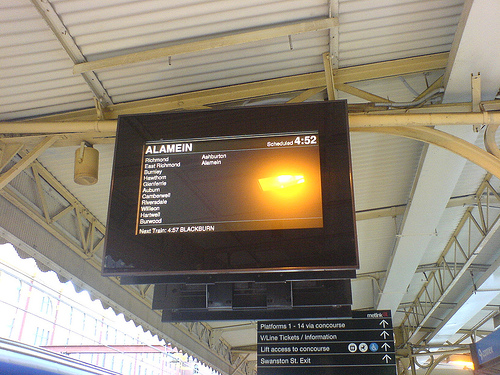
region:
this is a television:
[118, 116, 358, 273]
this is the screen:
[146, 143, 320, 218]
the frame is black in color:
[128, 108, 328, 128]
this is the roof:
[104, 21, 286, 62]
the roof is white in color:
[403, 211, 424, 245]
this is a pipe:
[382, 100, 424, 108]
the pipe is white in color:
[393, 101, 405, 107]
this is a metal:
[6, 134, 78, 225]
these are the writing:
[143, 154, 164, 224]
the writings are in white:
[148, 146, 179, 188]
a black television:
[100, 93, 364, 278]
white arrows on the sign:
[378, 313, 394, 369]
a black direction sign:
[254, 303, 399, 373]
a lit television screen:
[132, 124, 331, 246]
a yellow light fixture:
[69, 140, 102, 192]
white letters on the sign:
[258, 316, 350, 334]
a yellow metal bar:
[0, 105, 499, 140]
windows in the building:
[1, 241, 227, 373]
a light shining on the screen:
[246, 152, 322, 217]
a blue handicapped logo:
[368, 340, 380, 357]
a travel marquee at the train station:
[97, 113, 359, 276]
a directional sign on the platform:
[254, 320, 413, 374]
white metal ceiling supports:
[446, 234, 484, 269]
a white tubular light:
[74, 157, 103, 189]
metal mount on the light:
[77, 141, 83, 151]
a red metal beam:
[70, 340, 157, 356]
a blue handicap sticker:
[370, 337, 390, 357]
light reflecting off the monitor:
[243, 161, 323, 201]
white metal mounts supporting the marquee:
[321, 59, 349, 96]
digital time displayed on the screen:
[284, 129, 321, 151]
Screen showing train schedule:
[127, 114, 342, 269]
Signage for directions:
[258, 324, 399, 371]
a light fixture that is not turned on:
[71, 140, 96, 202]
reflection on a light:
[255, 166, 312, 209]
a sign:
[465, 317, 497, 372]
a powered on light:
[435, 345, 473, 373]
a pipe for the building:
[350, 105, 498, 126]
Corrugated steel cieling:
[42, 0, 309, 95]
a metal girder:
[51, 341, 161, 354]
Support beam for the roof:
[35, 46, 483, 134]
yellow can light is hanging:
[75, 145, 97, 186]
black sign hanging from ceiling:
[258, 309, 398, 373]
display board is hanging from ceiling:
[101, 100, 362, 274]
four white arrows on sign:
[379, 317, 395, 362]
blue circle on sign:
[368, 341, 380, 353]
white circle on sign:
[358, 342, 368, 352]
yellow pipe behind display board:
[0, 118, 116, 133]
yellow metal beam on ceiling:
[47, 50, 447, 118]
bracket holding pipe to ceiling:
[94, 97, 104, 132]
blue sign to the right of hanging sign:
[474, 327, 499, 366]